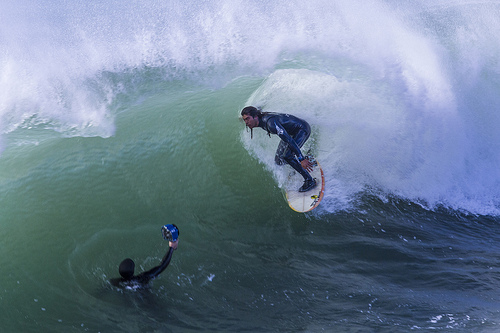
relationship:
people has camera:
[110, 223, 180, 293] [159, 223, 185, 241]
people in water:
[110, 223, 180, 293] [1, 71, 499, 332]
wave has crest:
[2, 1, 499, 220] [1, 0, 499, 219]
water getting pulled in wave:
[1, 71, 499, 332] [2, 1, 499, 220]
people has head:
[110, 223, 180, 293] [119, 256, 136, 279]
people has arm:
[110, 223, 180, 293] [141, 241, 179, 285]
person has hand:
[241, 107, 316, 194] [298, 157, 313, 171]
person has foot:
[241, 107, 316, 194] [299, 178, 322, 192]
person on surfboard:
[241, 107, 316, 194] [283, 169, 328, 214]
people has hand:
[110, 223, 180, 293] [168, 239, 181, 247]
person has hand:
[241, 105, 320, 194] [298, 157, 313, 171]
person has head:
[241, 105, 320, 194] [240, 105, 260, 129]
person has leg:
[241, 105, 320, 194] [284, 134, 320, 193]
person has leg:
[241, 105, 320, 194] [274, 138, 293, 166]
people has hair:
[110, 223, 180, 293] [118, 256, 144, 279]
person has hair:
[241, 105, 320, 194] [240, 105, 265, 120]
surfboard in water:
[283, 169, 328, 214] [1, 71, 499, 332]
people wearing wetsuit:
[110, 223, 180, 293] [110, 246, 179, 288]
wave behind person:
[2, 1, 499, 220] [241, 107, 316, 194]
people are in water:
[110, 105, 320, 293] [1, 71, 499, 332]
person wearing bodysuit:
[241, 107, 316, 194] [258, 111, 313, 180]